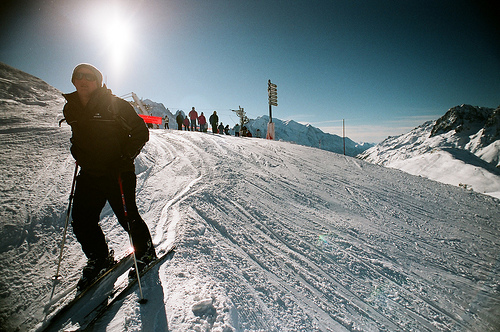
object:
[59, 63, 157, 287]
man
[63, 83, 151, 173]
coat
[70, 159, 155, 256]
pants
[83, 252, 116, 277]
shoes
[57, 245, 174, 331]
skis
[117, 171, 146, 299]
ski poles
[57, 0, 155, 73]
sun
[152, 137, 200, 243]
tracks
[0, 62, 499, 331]
snow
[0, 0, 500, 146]
sky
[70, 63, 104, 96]
head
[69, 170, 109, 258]
right leg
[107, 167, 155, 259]
left leg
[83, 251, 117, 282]
right foot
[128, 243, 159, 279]
left foot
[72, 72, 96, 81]
goggles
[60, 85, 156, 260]
snow clothes